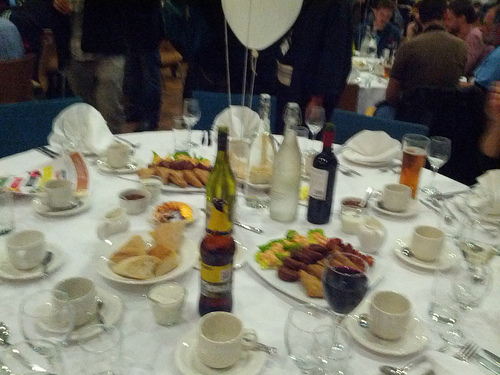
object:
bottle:
[306, 122, 338, 226]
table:
[0, 127, 498, 374]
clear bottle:
[268, 128, 302, 224]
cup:
[366, 290, 411, 342]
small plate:
[345, 311, 431, 356]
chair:
[326, 111, 420, 147]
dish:
[91, 228, 197, 285]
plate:
[174, 326, 270, 374]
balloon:
[218, 1, 303, 52]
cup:
[51, 274, 98, 328]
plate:
[34, 289, 122, 342]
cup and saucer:
[373, 183, 411, 212]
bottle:
[204, 126, 238, 237]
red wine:
[321, 267, 369, 315]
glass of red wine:
[321, 267, 369, 353]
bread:
[112, 255, 163, 280]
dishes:
[246, 224, 390, 308]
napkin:
[344, 128, 401, 167]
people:
[365, 31, 495, 185]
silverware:
[374, 354, 427, 375]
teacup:
[194, 310, 258, 371]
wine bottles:
[194, 92, 337, 320]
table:
[329, 38, 420, 112]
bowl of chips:
[148, 199, 196, 227]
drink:
[320, 266, 369, 314]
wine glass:
[419, 138, 451, 196]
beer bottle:
[197, 196, 235, 318]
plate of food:
[252, 227, 377, 301]